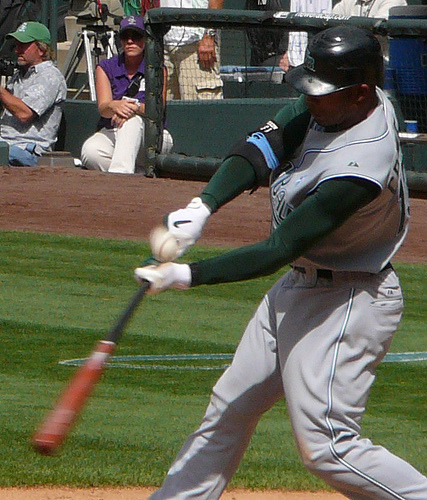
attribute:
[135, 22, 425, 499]
player — wearing, swinging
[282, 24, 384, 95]
helmet — black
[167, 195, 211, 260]
glove — batting glove, white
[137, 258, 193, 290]
glove — batting glove, white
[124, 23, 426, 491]
man — swinging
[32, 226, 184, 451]
bat — black, red, player's, mid-swing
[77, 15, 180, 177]
woman — watching, wearing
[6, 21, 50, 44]
hat — green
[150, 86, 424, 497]
uniform — grey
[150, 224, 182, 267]
ball — moving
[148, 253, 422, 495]
pants — player's, pair, grey, gray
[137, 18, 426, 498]
batter — swinging, left-handed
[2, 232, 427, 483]
grass — green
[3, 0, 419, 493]
sport — baseball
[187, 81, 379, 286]
under shirt — green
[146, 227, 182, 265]
baseball — coming, white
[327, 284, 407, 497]
stripe — white'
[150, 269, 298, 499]
leg — stiff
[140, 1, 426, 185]
railing — padded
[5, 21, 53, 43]
ball cap — green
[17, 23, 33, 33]
writing — white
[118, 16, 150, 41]
ball cap — purple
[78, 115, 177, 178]
pants — white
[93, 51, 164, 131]
shirt — purple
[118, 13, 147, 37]
cap — purple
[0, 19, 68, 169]
man — wearing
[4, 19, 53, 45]
cap — green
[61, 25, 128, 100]
tripod — set up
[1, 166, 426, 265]
patch — dirt, brown